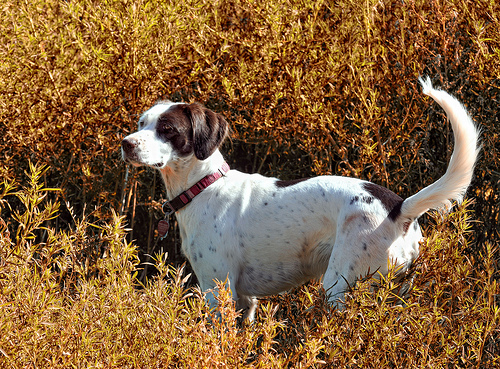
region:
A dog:
[201, 119, 343, 342]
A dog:
[251, 208, 338, 330]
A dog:
[248, 128, 313, 270]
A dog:
[220, 159, 305, 357]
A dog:
[185, 198, 235, 301]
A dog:
[203, 113, 265, 287]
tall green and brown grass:
[3, 155, 253, 367]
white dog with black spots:
[114, 77, 482, 305]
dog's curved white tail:
[399, 67, 480, 222]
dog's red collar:
[158, 158, 234, 210]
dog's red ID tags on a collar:
[153, 204, 173, 241]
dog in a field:
[78, 71, 480, 317]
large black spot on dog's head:
[153, 98, 230, 159]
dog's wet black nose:
[117, 137, 133, 150]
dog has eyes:
[134, 113, 180, 136]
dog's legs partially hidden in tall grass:
[177, 270, 463, 332]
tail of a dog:
[464, 142, 474, 172]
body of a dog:
[276, 265, 283, 272]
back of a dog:
[380, 240, 386, 245]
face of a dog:
[131, 140, 148, 159]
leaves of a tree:
[131, 297, 158, 309]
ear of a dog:
[209, 122, 210, 132]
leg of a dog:
[337, 242, 356, 297]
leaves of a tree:
[371, 145, 397, 166]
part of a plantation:
[149, 315, 172, 326]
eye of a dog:
[167, 122, 181, 139]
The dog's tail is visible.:
[414, 75, 496, 245]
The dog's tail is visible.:
[375, 47, 482, 247]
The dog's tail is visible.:
[347, 111, 447, 311]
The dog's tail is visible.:
[430, 60, 477, 227]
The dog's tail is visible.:
[430, 54, 497, 158]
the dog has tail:
[147, 69, 493, 257]